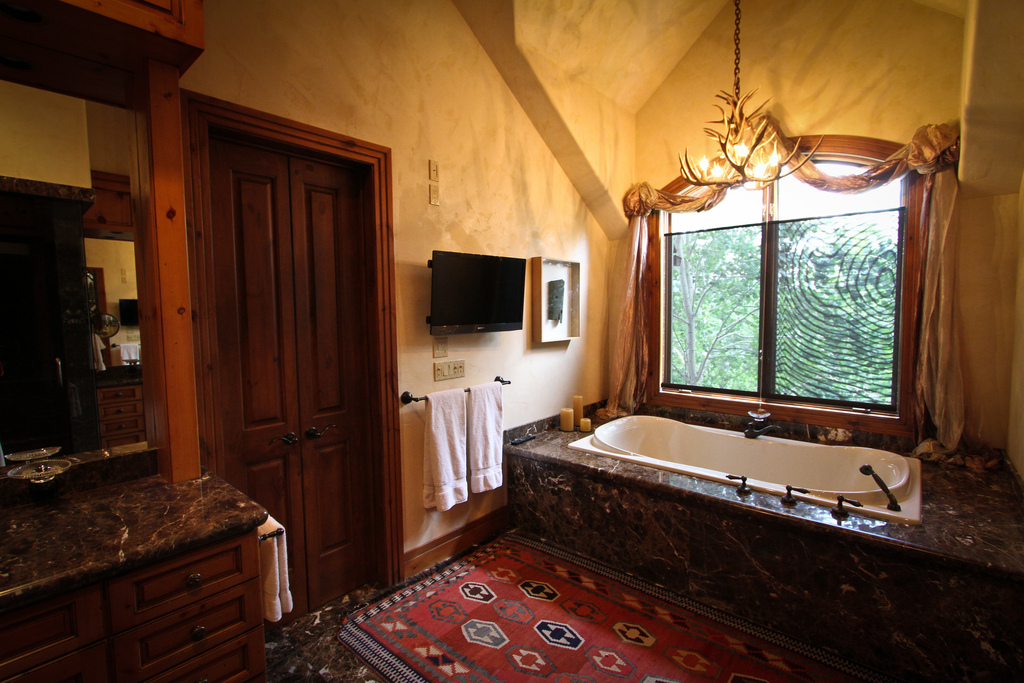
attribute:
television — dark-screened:
[405, 242, 539, 347]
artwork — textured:
[571, 242, 629, 347]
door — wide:
[183, 104, 544, 632]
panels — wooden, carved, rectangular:
[201, 202, 399, 415]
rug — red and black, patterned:
[400, 548, 781, 672]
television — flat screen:
[384, 251, 559, 369]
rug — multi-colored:
[369, 532, 769, 653]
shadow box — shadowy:
[536, 273, 607, 332]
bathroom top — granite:
[2, 471, 269, 612]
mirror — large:
[31, 83, 188, 360]